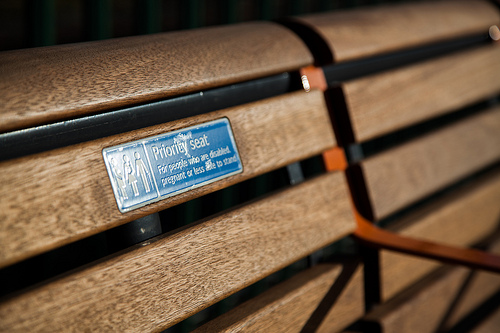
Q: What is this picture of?
A: Bench.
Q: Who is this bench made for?
A: Disabled people.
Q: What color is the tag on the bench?
A: Blue.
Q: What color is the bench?
A: Brown.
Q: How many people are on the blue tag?
A: Three.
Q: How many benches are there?
A: Two.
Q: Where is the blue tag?
A: On the back of the first bench.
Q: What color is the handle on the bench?
A: Orange.